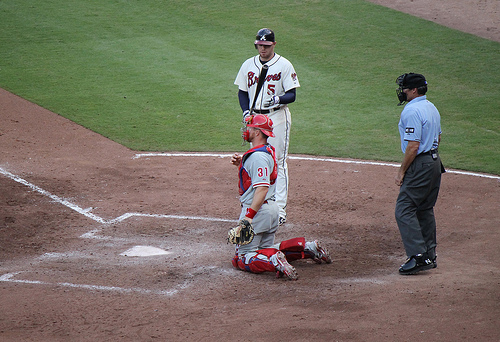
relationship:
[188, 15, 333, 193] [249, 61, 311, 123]
player holding bat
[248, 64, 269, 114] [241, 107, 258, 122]
baseball bat in hand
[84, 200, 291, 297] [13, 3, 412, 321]
batter's box on baseball field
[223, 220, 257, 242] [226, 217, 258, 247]
glove in a hand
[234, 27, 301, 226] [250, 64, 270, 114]
man holding bat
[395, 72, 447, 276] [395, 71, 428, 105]
man wearing face mask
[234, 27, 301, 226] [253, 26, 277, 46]
man wearing hat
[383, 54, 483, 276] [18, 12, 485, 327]
man standing on field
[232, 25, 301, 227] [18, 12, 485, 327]
man standing on field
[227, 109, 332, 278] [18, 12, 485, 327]
man kneeling on field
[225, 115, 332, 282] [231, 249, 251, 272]
catcher sitting on knee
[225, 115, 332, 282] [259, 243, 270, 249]
catcher sitting on knee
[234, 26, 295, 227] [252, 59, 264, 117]
batter holding bat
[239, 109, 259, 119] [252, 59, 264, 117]
hand holding bat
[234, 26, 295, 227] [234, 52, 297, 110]
batter wearing shirt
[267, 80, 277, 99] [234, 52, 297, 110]
number sewn on shirt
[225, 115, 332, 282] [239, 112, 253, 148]
catcher wearing face mask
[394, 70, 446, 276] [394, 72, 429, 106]
umpire wearing mask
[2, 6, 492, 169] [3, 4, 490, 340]
grass growing on field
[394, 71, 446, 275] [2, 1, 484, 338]
umpire officiating baseball game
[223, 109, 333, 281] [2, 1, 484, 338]
catcher playing baseball game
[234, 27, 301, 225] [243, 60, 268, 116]
player holding bat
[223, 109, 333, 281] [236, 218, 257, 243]
catcher wearing glove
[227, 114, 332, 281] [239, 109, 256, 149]
man wearing mask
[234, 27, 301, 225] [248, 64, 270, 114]
player holding baseball bat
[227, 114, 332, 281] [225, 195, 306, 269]
man wearing grey pants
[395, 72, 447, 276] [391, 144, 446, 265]
man wearing grey pants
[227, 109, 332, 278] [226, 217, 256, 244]
man wearing glove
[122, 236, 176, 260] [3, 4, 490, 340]
plate lying on top of field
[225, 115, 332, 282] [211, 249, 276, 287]
catcher wearing shin guard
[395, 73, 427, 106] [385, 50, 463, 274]
face mask of umpire